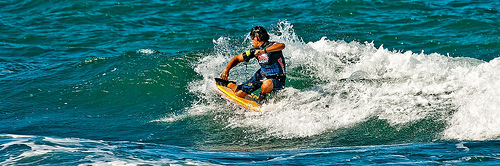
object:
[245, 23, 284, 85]
man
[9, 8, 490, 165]
ocean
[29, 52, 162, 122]
waves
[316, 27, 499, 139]
water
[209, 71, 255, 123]
surfboard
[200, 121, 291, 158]
shadow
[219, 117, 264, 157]
bubbles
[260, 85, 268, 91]
knee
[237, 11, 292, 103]
surfer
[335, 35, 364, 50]
breaks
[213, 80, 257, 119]
board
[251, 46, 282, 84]
wetsuit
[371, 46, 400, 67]
cap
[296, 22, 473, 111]
wave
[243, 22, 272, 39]
hair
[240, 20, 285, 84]
boarder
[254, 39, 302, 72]
arm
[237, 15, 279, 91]
rider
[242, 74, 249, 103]
knee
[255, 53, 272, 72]
advertisements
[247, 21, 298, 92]
person